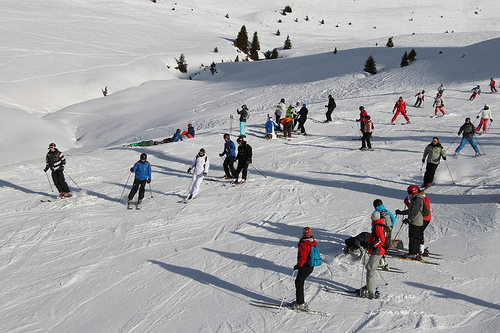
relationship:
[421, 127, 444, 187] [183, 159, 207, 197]
person with white snowgear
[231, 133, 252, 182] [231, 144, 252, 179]
skier with snowgear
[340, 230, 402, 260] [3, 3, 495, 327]
snowboarder on ground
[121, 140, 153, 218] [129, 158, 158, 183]
person on jacket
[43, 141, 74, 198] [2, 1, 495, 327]
person in snow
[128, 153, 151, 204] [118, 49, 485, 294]
man in slopes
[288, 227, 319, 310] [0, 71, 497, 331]
people in slope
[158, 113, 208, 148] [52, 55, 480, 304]
couple in slopes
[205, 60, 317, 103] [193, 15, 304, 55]
snowy tundra has trees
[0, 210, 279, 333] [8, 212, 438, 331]
snow on ground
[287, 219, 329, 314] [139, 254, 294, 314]
skier has shadow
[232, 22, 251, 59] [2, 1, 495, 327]
tree in snow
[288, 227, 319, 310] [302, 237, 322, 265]
people wears backpack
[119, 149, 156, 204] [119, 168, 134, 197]
man holds ski pole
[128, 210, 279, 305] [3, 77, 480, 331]
snow on ground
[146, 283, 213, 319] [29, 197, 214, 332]
tracks are in snow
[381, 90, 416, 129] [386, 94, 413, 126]
person wearing ski suit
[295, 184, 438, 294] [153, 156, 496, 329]
people on ski slope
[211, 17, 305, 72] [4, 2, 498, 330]
trees on ski slope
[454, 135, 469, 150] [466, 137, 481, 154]
leg far apart from leg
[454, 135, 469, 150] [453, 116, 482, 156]
leg of person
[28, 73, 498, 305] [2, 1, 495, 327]
skiers in snow